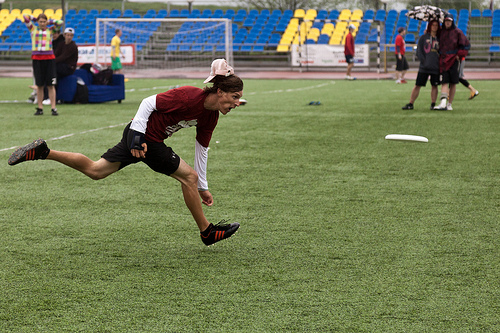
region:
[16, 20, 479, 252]
People are in ground.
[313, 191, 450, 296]
Grass is green color.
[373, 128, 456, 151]
Frisbee is in air.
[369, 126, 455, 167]
Frisbee is white color.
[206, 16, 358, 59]
Chairs are blue and yellow.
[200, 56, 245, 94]
Cap is brown color.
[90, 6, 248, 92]
Net is white color.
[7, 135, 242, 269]
Boy is wearing black and red shoes.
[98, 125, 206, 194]
Boy is wearing black shorts.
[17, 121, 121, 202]
White lines in ground.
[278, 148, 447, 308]
a ground with full of green grass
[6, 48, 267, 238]
a man is running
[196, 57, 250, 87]
a hat on the man's head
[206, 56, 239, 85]
a cream colour hat on the man's head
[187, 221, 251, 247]
a man weared black colour shoe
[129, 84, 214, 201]
brown with white colour t-shirt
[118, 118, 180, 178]
a man wearing black colour shorts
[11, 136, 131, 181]
a man lifting his leg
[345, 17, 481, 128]
some persons walking and standing in the ground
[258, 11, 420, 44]
blue and yellow colour chairs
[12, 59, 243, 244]
man running on feild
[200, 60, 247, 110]
man's hat is falling off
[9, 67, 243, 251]
man wearing black shoes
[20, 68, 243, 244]
man wearing black shorts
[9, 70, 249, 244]
man wearing black glove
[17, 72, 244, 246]
man wearing red shirt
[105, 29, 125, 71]
man standing in goal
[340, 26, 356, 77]
man wearing black shorts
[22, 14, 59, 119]
man wearing black shorts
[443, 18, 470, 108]
man wearing black shorts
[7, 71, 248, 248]
Man is running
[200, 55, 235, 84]
Pink hat on man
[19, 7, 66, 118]
Woman wearing colorful sweater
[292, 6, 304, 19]
Seat is yellow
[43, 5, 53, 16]
Seat is yellow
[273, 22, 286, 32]
Seat is bright blue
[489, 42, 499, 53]
Seat is bright blue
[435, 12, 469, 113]
Man holding umbrella over man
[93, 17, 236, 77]
White soccer net by man in yellow shirt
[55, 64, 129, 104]
Blue sofa behind man in white hat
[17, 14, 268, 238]
the man is running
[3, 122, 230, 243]
man's shoes are black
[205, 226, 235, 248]
red stripes on shoes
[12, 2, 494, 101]
men are watching other man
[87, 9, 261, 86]
a net is in background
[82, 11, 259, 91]
the net is white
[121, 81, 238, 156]
man's shirt is red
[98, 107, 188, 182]
man's shorts are black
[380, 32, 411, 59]
man's shirt is red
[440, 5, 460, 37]
man has hood on